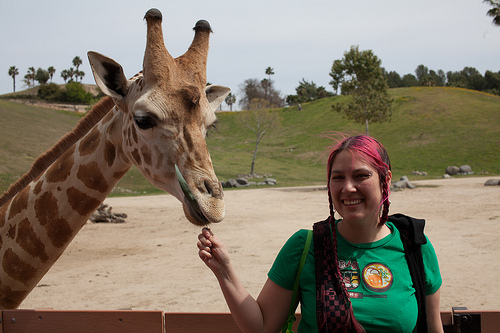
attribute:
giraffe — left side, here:
[0, 7, 232, 310]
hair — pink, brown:
[320, 128, 394, 331]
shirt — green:
[267, 218, 442, 332]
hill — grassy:
[0, 82, 500, 196]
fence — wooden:
[0, 307, 499, 332]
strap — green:
[284, 229, 315, 333]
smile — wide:
[340, 196, 367, 207]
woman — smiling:
[197, 129, 445, 332]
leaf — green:
[172, 163, 210, 222]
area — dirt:
[17, 174, 499, 313]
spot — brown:
[75, 158, 111, 193]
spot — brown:
[44, 142, 77, 183]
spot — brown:
[78, 124, 103, 157]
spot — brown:
[65, 184, 102, 216]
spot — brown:
[33, 191, 75, 250]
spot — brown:
[15, 217, 50, 263]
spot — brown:
[1, 246, 38, 287]